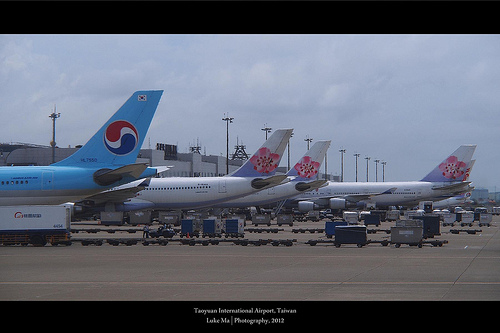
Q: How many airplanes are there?
A: Four.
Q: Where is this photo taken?
A: An airport.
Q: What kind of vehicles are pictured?
A: Airplanes.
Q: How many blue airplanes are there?
A: One.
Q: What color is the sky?
A: Blue.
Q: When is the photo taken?
A: Day time.